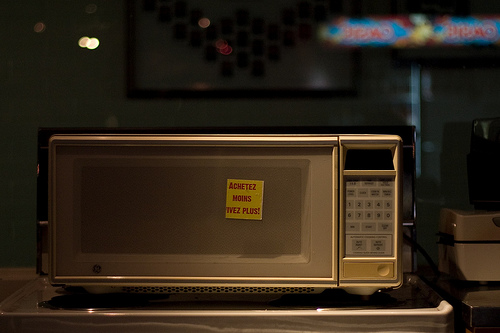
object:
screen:
[344, 148, 396, 171]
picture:
[126, 0, 360, 98]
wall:
[1, 1, 414, 125]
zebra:
[34, 125, 406, 295]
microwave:
[36, 126, 417, 310]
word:
[226, 206, 263, 214]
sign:
[319, 12, 499, 47]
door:
[50, 135, 338, 283]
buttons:
[346, 197, 354, 208]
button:
[341, 261, 393, 278]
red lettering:
[231, 193, 253, 202]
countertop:
[1, 273, 453, 314]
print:
[225, 178, 263, 219]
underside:
[37, 285, 169, 310]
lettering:
[227, 181, 256, 189]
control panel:
[344, 173, 396, 258]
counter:
[0, 274, 454, 332]